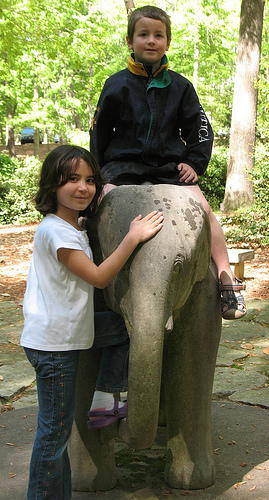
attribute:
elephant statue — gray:
[69, 184, 223, 491]